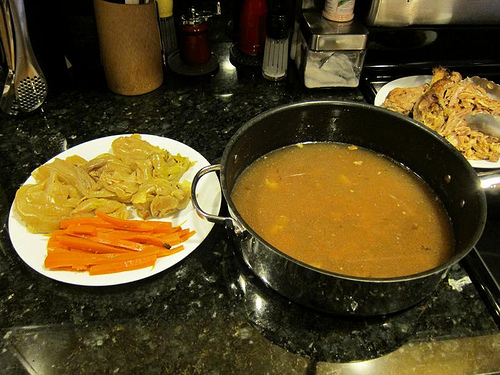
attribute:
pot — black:
[224, 103, 484, 316]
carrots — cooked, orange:
[45, 214, 196, 277]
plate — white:
[10, 133, 222, 289]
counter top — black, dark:
[3, 73, 500, 374]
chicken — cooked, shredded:
[398, 74, 469, 119]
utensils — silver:
[3, 18, 48, 118]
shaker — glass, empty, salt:
[263, 15, 294, 83]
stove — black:
[366, 29, 499, 82]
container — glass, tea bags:
[296, 14, 372, 92]